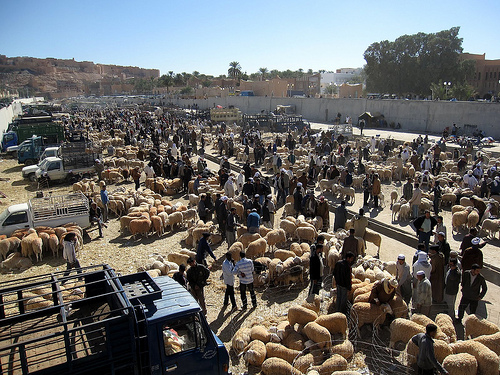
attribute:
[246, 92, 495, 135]
wall — grey, barrier, tall, cement, large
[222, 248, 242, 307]
person — hugging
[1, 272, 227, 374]
truck — black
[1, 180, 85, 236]
truck — white, crated, parked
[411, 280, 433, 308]
shirt — grey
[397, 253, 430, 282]
hats — white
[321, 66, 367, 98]
building — white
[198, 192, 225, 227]
people — talking, different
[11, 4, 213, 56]
sky — blue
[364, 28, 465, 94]
trees — green, leafy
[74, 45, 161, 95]
hills — high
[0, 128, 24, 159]
truck — blue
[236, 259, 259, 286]
shirt — striped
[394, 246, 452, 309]
men — looking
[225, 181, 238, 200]
shirt — white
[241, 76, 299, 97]
building — tan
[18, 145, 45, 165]
truck — blue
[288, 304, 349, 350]
sheep — eating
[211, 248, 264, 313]
couple — loving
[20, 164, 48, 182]
truck — white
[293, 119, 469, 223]
people — walking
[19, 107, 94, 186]
trucks — ready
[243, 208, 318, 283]
sheep — numerous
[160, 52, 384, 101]
buildings — here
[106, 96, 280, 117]
fence — large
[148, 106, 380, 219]
crowd — large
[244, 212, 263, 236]
shirt — blue